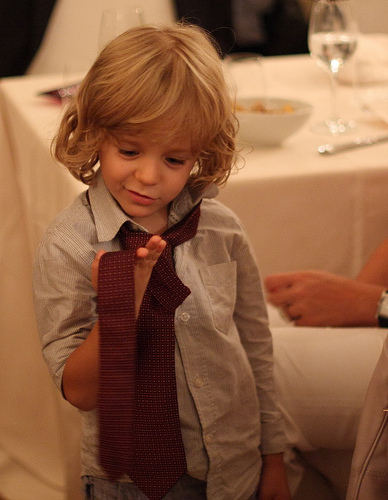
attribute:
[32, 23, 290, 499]
boy — little, looking, smirking, young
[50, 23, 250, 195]
hair — long, curly, blonde, dirty, blond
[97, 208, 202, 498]
tie — red, untied, burgundy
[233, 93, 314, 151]
bowl — white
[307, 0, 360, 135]
glass — wine glass, half-full, clear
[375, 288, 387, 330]
watch — black, wrist watch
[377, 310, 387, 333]
band — black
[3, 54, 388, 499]
table — round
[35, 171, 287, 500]
shirt — brown, gray, grey, long sleeved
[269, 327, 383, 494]
pants — white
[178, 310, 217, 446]
buttons — white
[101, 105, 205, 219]
face — smiling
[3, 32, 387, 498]
table cloth — peach